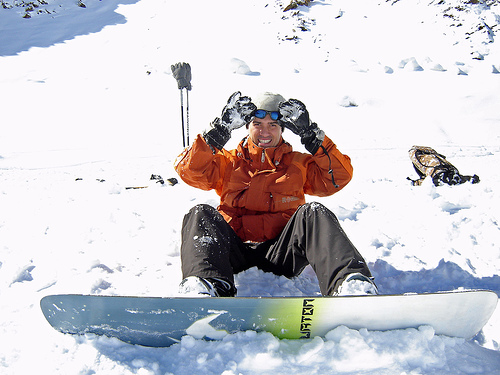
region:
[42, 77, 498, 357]
man sitting on the snow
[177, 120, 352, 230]
orange snow jacket on man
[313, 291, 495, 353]
white bottom of board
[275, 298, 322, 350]
yellow and black bottom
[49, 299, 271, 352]
blue bottom to board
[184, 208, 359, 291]
black pants on man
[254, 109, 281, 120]
blue snow goggles on face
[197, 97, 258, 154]
black gloves on hand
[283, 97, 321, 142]
black snow glvoe on hand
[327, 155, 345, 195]
black zipper on jacket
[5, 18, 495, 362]
The mountain is covered in snow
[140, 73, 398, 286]
The man is sitting down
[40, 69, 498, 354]
He is wearing a snowboard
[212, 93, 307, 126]
He is wearing sunglasses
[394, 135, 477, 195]
A backpack in the snow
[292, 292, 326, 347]
Snowboard made by Burton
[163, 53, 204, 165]
Ski poles stuck in the snow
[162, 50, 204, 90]
Gloves on the top of the ski poles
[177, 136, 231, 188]
the arm of the snowboarder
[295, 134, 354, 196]
the arm of the snowboarder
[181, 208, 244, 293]
the leg of the snowboarder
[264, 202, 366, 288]
the leg of the snowboarder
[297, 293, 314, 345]
the black lettering on the snowboard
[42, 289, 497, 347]
the yellow blue and white snowboard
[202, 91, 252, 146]
the black snow covered gloves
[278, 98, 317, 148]
the black snow covered gloves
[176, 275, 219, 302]
the snow covered boots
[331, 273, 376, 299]
the snow covered boots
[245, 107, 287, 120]
sunglasses on the man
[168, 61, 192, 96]
gloves on the ski pole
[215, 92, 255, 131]
glove on the hand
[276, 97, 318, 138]
glove on the hand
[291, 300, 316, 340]
words on the snow board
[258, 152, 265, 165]
zipper on the jacket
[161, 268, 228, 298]
snow boot on the man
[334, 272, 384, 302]
snow boot on the man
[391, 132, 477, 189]
jacket in the snow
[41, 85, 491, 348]
man sitting in the snow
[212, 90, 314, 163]
head of the man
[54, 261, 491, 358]
board under the man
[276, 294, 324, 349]
black writing on board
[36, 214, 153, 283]
white snow on the ground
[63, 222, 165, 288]
snow next to man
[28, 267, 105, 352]
end of the board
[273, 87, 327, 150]
hand of the person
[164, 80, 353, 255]
person in orange outfit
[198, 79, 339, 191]
man looking at the camera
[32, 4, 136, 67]
shadow in the background